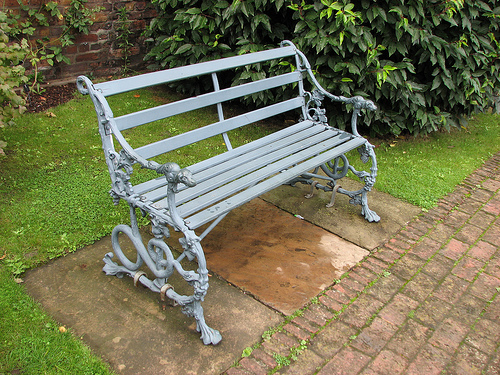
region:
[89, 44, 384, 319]
gray bench sitting by sidewalk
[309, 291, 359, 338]
green moss between bricks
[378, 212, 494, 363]
red bricks of sidewalk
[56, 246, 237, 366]
concrete slabs below bench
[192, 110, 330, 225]
wooden seat of bench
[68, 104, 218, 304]
metal arms of bench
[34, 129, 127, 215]
green grass growing on ground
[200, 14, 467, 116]
thick bushes next to bench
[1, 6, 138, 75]
brick wall of building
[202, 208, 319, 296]
wet spots on ground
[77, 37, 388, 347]
gray park bench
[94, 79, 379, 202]
armrests on the gray bench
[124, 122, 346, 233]
seat of the gray bench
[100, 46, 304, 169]
back of the gray bench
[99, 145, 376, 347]
legs of the bench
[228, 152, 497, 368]
brick walkway in front of bench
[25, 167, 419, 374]
cement pad the bench is on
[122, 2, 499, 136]
bush beside the bench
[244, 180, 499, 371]
weeds growing through the brick walkway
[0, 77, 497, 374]
grass growing around the walkway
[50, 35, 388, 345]
a bench color blue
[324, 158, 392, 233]
right leg of bench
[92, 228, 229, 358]
left leg of bench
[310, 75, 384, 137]
right armrest of bench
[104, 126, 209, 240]
left armrest of bench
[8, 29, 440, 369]
green grass around the bench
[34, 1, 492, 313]
a bush on left of bench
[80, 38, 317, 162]
three planks on backrest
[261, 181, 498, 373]
red bricks on sidewalk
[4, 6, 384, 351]
a wall behind a bench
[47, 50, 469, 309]
a bench in the forest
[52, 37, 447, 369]
a bench in the park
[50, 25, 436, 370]
a bench in the ground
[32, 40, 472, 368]
a bench in the floor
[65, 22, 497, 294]
a bench in the grass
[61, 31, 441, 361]
a bench in the stone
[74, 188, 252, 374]
leg of the bench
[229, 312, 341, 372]
a part of green grass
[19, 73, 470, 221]
a clean view of grass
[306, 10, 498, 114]
group of trees near bench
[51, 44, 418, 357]
metal bench on concrete pavers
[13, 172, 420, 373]
concrete pavers under bench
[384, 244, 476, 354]
red brick pathway in front of bench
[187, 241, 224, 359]
leg of a bench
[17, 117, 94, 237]
green grass by the bench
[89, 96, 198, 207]
arm of a bench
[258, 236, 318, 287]
wet spot on a paver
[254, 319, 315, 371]
grass coming through the bricks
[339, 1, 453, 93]
green leaves on bushes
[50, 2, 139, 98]
brick wall behind bench